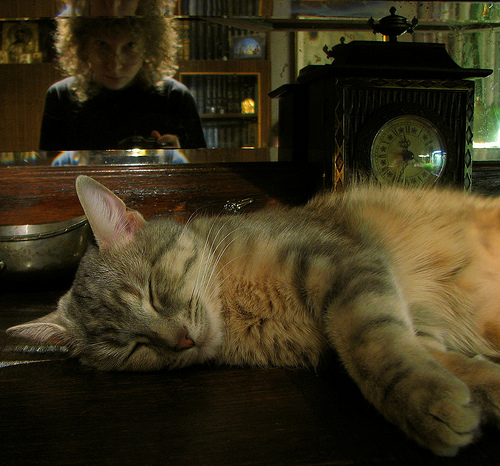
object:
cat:
[6, 165, 498, 457]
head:
[6, 172, 222, 373]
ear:
[75, 172, 152, 259]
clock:
[367, 111, 445, 196]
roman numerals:
[404, 122, 414, 136]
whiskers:
[173, 214, 250, 340]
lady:
[37, 0, 209, 149]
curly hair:
[51, 0, 181, 98]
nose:
[170, 331, 195, 355]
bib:
[219, 268, 332, 370]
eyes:
[114, 336, 153, 375]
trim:
[348, 95, 456, 197]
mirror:
[0, 0, 499, 168]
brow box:
[289, 12, 498, 161]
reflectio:
[0, 1, 267, 31]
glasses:
[70, 40, 147, 69]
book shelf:
[155, 0, 268, 161]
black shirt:
[37, 71, 207, 148]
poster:
[0, 15, 45, 65]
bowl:
[1, 209, 95, 274]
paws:
[411, 372, 476, 460]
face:
[68, 221, 220, 367]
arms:
[397, 158, 410, 183]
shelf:
[0, 273, 499, 465]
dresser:
[0, 155, 499, 466]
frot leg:
[300, 222, 476, 457]